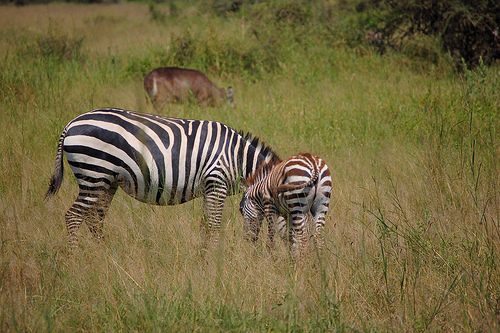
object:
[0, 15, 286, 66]
bush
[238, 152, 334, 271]
zebra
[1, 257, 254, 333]
grass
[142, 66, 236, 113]
animals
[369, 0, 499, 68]
branches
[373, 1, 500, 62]
tree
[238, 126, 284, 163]
mane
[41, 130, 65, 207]
tail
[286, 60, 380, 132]
field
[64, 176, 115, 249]
leg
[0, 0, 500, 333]
plain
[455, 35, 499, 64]
shadow